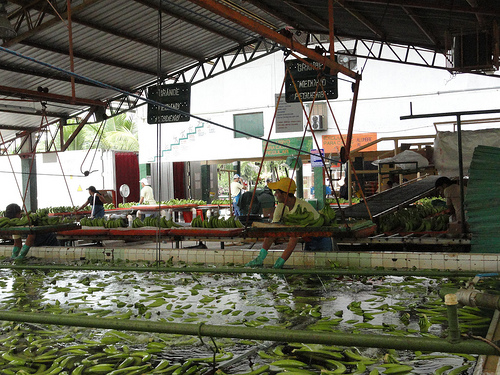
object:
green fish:
[271, 359, 306, 366]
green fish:
[385, 365, 412, 374]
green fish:
[208, 350, 234, 363]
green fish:
[309, 307, 320, 314]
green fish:
[86, 361, 113, 371]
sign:
[270, 90, 309, 134]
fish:
[108, 333, 178, 373]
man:
[249, 175, 335, 272]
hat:
[265, 175, 295, 193]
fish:
[319, 284, 388, 333]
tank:
[43, 217, 497, 372]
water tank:
[20, 250, 450, 372]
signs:
[142, 47, 344, 128]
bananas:
[263, 197, 377, 250]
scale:
[150, 5, 400, 261]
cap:
[266, 174, 296, 194]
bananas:
[0, 200, 238, 227]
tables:
[0, 218, 382, 245]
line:
[146, 118, 212, 163]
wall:
[137, 46, 499, 160]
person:
[73, 180, 100, 217]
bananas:
[4, 245, 499, 374]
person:
[261, 184, 333, 253]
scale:
[111, 175, 160, 212]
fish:
[318, 351, 345, 370]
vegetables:
[114, 200, 164, 210]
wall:
[266, 91, 315, 137]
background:
[53, 175, 141, 221]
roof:
[144, 13, 384, 62]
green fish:
[9, 273, 437, 369]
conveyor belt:
[344, 159, 450, 238]